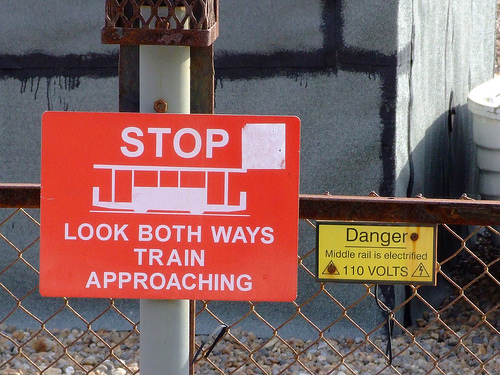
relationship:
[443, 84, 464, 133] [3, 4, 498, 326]
circle in building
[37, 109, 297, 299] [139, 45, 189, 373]
sign on pole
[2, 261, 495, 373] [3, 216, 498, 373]
gravel covering ground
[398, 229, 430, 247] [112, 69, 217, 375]
bolt on pole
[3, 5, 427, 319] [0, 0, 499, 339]
sealer on building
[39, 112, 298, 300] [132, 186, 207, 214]
sign for train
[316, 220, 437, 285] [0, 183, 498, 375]
sign for cage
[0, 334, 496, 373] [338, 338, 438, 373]
gravel on ground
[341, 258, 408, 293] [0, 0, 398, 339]
marking on sealer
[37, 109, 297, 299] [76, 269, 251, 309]
sign has writing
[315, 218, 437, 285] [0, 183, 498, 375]
sign on cage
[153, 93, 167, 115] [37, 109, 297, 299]
bolt above sign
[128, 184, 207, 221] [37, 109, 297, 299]
train on sign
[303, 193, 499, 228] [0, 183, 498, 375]
rail on top of cage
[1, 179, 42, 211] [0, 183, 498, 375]
rail on top of cage